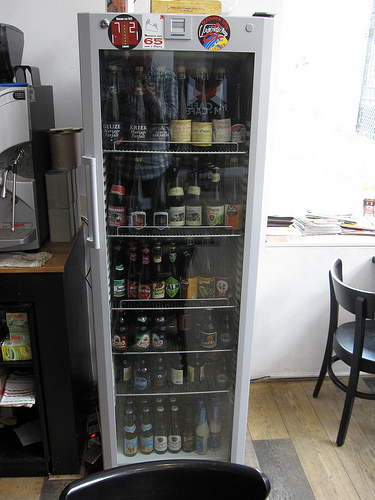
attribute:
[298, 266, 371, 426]
chair — black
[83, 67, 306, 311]
fridge — tall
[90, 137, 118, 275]
handle — silver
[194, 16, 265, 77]
sticker — round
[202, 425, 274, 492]
basket — black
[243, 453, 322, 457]
floor — wooden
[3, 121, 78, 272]
machine — grey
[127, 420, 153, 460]
label — blue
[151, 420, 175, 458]
label — white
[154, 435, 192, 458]
towel — white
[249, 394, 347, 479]
floor — wooden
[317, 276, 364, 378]
chairs — black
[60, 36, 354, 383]
cooler — grey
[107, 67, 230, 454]
bottles — beer 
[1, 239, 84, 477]
table — black , wooden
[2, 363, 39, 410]
towels — blue , white, red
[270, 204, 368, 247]
shelf — white 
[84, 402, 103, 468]
outlet — electrical 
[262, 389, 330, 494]
floor — hardwood 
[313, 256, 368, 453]
chair — black 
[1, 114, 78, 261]
machine — espresso 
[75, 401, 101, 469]
outlet — power 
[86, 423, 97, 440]
light — red 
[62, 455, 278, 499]
chair — black 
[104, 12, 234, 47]
stickers — three 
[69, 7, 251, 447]
refrigerator — one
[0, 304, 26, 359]
tea — herbal 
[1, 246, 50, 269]
napkin — dirty 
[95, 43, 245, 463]
door — glass 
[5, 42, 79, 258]
machine — gray , black , coffee , commercial , espresso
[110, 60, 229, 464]
beverages — some, bottled 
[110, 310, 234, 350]
beverages — bottled 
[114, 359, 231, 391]
beverages — bottled 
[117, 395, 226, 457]
beverages — bottled 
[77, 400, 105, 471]
strip — power, electric